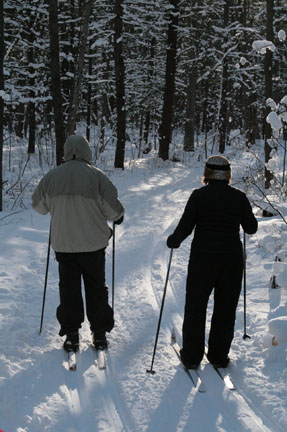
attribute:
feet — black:
[61, 329, 112, 350]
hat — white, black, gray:
[202, 154, 233, 185]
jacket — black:
[171, 185, 259, 259]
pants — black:
[181, 259, 239, 365]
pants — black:
[52, 251, 120, 352]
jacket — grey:
[32, 135, 125, 250]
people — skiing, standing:
[30, 128, 256, 371]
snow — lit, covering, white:
[5, 127, 286, 430]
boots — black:
[183, 341, 234, 371]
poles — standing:
[148, 237, 254, 373]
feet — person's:
[172, 341, 241, 370]